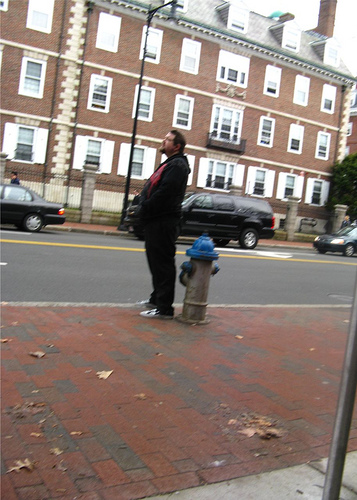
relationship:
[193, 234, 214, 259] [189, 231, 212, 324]
top on hydrant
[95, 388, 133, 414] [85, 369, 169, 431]
bricks in sidewalk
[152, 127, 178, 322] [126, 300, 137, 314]
man on curb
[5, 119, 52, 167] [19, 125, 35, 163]
shutters around window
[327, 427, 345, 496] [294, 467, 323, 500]
pole in sidewalk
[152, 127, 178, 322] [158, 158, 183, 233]
man wearing hoodie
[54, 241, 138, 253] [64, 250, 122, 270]
line marking road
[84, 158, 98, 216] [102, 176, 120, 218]
column supporting fence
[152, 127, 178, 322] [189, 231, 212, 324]
man next to hydrant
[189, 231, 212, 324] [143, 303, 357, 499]
hydrant on side walk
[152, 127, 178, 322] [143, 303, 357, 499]
man standing on side walk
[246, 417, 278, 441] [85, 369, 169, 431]
leaves on sidewalk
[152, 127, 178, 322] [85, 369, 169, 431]
man on sidewalk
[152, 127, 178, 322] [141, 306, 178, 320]
man wearing shoes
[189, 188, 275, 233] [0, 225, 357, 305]
suv parked across road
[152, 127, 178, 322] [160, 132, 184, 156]
man looking upward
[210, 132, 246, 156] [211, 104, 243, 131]
balcony under window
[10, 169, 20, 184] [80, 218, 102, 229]
person walking sidewalk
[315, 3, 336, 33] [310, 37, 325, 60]
chimney on roof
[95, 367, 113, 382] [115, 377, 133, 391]
leaf on ground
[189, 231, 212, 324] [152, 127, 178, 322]
hydrant behind man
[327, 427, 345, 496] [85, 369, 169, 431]
pole in front of sidewalk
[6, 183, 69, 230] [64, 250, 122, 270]
car parked on road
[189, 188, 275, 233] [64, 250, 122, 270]
car parked on road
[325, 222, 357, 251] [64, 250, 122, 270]
car parked on road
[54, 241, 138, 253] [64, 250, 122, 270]
line on road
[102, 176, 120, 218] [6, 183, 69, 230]
fence behind car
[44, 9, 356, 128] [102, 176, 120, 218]
building behind fence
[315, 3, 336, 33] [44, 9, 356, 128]
chimney on building